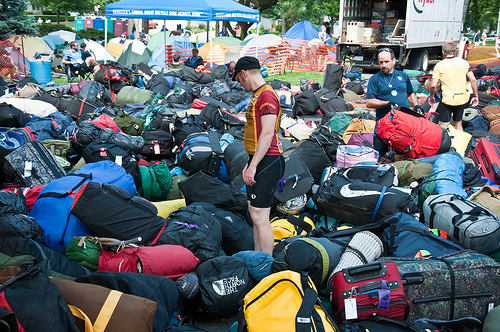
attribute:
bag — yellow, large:
[238, 267, 338, 331]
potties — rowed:
[73, 15, 128, 36]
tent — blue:
[95, 0, 273, 74]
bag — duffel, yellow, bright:
[248, 272, 334, 330]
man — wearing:
[371, 48, 411, 104]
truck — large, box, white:
[333, 0, 475, 72]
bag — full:
[321, 168, 416, 225]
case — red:
[325, 259, 409, 324]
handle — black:
[345, 261, 383, 276]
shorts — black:
[243, 151, 291, 211]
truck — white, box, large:
[333, 0, 468, 61]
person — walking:
[480, 27, 488, 46]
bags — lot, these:
[60, 123, 245, 301]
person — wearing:
[426, 39, 490, 154]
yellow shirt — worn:
[428, 58, 480, 110]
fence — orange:
[145, 24, 350, 90]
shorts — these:
[246, 154, 286, 205]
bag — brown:
[50, 276, 161, 330]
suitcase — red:
[329, 256, 410, 330]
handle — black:
[349, 257, 384, 284]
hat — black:
[215, 55, 270, 81]